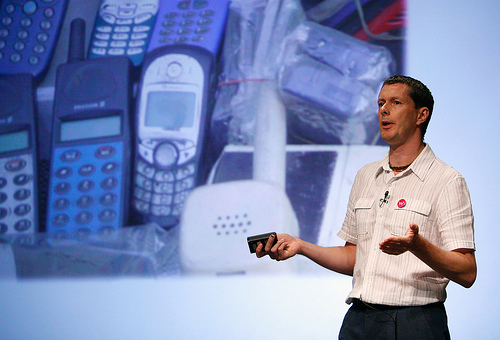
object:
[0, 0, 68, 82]
cellphones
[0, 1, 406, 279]
picture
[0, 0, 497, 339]
wall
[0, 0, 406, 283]
slide show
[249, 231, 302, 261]
hand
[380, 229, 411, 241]
palm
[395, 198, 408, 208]
logo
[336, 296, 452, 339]
black slacks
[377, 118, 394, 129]
mouth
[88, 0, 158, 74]
cell phone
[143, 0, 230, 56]
cell phone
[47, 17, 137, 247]
cell phone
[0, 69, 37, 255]
cell phone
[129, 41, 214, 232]
cell phone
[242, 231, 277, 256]
phone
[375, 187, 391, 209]
microphone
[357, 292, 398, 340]
wire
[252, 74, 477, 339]
man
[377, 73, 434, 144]
short hair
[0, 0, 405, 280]
screen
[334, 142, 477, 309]
shirt